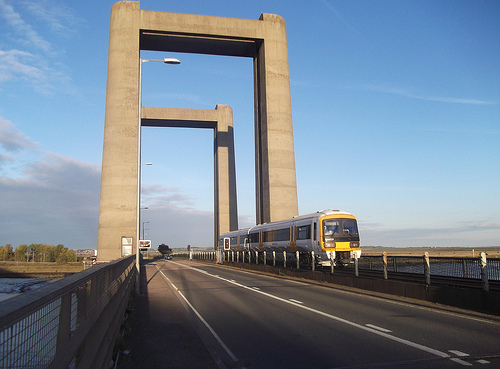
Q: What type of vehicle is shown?
A: Train.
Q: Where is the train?
A: Bridge.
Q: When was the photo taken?
A: Daytime.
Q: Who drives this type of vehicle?
A: Conductor.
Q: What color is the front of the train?
A: Yellow.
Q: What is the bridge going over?
A: Water.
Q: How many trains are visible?
A: One.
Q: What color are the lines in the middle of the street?
A: White.